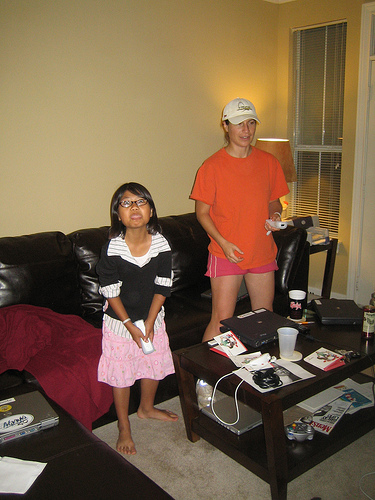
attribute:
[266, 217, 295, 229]
wii — game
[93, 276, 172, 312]
girl — no shoes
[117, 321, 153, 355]
controller — game cube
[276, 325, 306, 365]
cup — plastic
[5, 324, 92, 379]
blanket — red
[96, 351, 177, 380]
skirt — pink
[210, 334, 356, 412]
table — brown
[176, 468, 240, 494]
carpet — bare, tan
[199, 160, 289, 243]
t-shirt — orange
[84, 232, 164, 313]
top — dark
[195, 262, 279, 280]
shorts — pink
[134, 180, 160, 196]
hair — brown